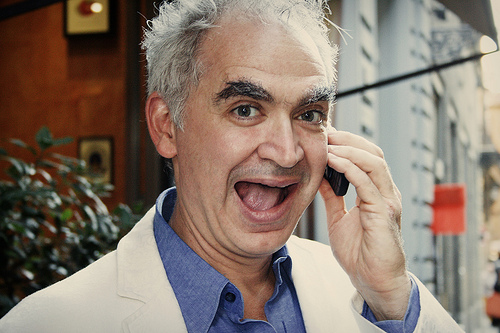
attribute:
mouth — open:
[226, 165, 308, 226]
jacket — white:
[35, 231, 233, 323]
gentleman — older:
[47, 4, 354, 278]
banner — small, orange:
[423, 183, 468, 235]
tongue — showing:
[219, 174, 296, 222]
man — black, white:
[131, 15, 496, 315]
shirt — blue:
[140, 185, 309, 330]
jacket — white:
[4, 174, 474, 330]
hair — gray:
[141, 1, 352, 141]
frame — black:
[69, 125, 125, 197]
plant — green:
[0, 122, 140, 306]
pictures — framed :
[56, 2, 126, 198]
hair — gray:
[136, 0, 353, 131]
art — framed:
[77, 135, 111, 200]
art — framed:
[62, 5, 109, 42]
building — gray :
[315, 13, 498, 283]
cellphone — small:
[323, 162, 349, 194]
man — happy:
[6, 0, 471, 330]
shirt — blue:
[160, 193, 308, 330]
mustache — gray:
[226, 163, 307, 183]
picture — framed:
[79, 131, 116, 200]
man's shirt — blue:
[146, 227, 308, 331]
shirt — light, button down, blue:
[151, 183, 416, 328]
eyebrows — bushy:
[213, 77, 335, 105]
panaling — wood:
[4, 2, 119, 278]